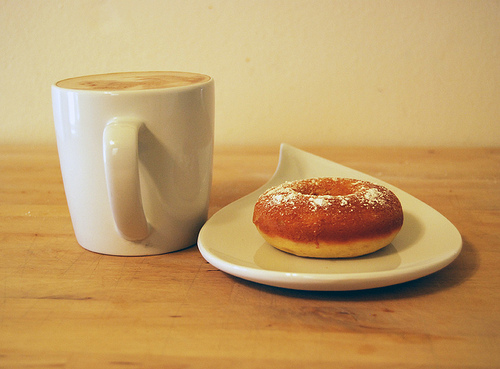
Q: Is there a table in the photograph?
A: Yes, there is a table.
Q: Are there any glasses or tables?
A: Yes, there is a table.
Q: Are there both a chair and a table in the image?
A: No, there is a table but no chairs.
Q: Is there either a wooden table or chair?
A: Yes, there is a wood table.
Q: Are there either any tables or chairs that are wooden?
A: Yes, the table is wooden.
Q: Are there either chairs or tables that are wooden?
A: Yes, the table is wooden.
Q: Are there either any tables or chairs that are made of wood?
A: Yes, the table is made of wood.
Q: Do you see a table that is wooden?
A: Yes, there is a wood table.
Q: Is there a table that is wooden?
A: Yes, there is a table that is wooden.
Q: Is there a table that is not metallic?
A: Yes, there is a wooden table.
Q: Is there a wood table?
A: Yes, there is a table that is made of wood.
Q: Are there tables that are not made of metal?
A: Yes, there is a table that is made of wood.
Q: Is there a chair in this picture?
A: No, there are no chairs.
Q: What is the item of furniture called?
A: The piece of furniture is a table.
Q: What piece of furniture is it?
A: The piece of furniture is a table.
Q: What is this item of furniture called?
A: This is a table.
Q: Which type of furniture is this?
A: This is a table.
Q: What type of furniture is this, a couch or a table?
A: This is a table.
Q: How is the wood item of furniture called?
A: The piece of furniture is a table.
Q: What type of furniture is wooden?
A: The furniture is a table.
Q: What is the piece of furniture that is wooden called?
A: The piece of furniture is a table.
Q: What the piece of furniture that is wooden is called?
A: The piece of furniture is a table.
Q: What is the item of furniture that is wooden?
A: The piece of furniture is a table.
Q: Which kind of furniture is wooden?
A: The furniture is a table.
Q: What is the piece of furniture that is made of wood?
A: The piece of furniture is a table.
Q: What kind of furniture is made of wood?
A: The furniture is a table.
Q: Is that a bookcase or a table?
A: That is a table.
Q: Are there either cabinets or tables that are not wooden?
A: No, there is a table but it is wooden.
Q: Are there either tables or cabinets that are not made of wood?
A: No, there is a table but it is made of wood.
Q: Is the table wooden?
A: Yes, the table is wooden.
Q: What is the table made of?
A: The table is made of wood.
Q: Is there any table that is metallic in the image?
A: No, there is a table but it is wooden.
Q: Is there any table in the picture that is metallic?
A: No, there is a table but it is wooden.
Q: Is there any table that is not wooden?
A: No, there is a table but it is wooden.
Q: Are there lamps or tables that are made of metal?
A: No, there is a table but it is made of wood.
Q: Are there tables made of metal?
A: No, there is a table but it is made of wood.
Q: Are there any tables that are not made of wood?
A: No, there is a table but it is made of wood.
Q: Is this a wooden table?
A: Yes, this is a wooden table.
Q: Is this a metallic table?
A: No, this is a wooden table.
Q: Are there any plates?
A: Yes, there is a plate.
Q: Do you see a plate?
A: Yes, there is a plate.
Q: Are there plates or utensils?
A: Yes, there is a plate.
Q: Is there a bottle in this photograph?
A: No, there are no bottles.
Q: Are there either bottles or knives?
A: No, there are no bottles or knives.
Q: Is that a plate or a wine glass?
A: That is a plate.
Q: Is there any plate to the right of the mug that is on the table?
A: Yes, there is a plate to the right of the mug.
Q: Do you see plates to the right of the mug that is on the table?
A: Yes, there is a plate to the right of the mug.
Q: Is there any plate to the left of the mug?
A: No, the plate is to the right of the mug.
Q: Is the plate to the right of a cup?
A: No, the plate is to the right of a mug.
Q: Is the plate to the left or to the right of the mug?
A: The plate is to the right of the mug.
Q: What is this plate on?
A: The plate is on the table.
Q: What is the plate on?
A: The plate is on the table.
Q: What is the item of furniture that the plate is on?
A: The piece of furniture is a table.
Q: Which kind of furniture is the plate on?
A: The plate is on the table.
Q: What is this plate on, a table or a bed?
A: The plate is on a table.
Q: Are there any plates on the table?
A: Yes, there is a plate on the table.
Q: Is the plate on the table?
A: Yes, the plate is on the table.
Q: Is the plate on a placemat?
A: No, the plate is on the table.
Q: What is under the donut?
A: The plate is under the donut.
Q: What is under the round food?
A: The plate is under the donut.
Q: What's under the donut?
A: The plate is under the donut.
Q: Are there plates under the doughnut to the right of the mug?
A: Yes, there is a plate under the donut.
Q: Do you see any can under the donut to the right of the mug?
A: No, there is a plate under the doughnut.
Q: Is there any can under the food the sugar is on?
A: No, there is a plate under the doughnut.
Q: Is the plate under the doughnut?
A: Yes, the plate is under the doughnut.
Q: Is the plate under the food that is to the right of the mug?
A: Yes, the plate is under the doughnut.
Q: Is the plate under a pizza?
A: No, the plate is under the doughnut.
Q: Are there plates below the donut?
A: Yes, there is a plate below the donut.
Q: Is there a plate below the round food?
A: Yes, there is a plate below the donut.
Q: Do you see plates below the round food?
A: Yes, there is a plate below the donut.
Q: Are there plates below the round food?
A: Yes, there is a plate below the donut.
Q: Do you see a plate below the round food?
A: Yes, there is a plate below the donut.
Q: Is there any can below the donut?
A: No, there is a plate below the donut.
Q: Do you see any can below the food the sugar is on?
A: No, there is a plate below the donut.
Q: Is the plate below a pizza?
A: No, the plate is below a donut.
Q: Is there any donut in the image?
A: Yes, there is a donut.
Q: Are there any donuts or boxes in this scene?
A: Yes, there is a donut.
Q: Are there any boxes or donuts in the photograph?
A: Yes, there is a donut.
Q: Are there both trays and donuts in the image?
A: No, there is a donut but no trays.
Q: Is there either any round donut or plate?
A: Yes, there is a round donut.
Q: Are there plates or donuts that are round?
A: Yes, the donut is round.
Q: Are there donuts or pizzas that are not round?
A: No, there is a donut but it is round.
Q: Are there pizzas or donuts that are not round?
A: No, there is a donut but it is round.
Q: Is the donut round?
A: Yes, the donut is round.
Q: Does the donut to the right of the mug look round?
A: Yes, the doughnut is round.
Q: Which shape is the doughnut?
A: The doughnut is round.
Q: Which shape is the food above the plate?
A: The doughnut is round.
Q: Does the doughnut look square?
A: No, the doughnut is round.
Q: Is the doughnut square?
A: No, the doughnut is round.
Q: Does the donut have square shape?
A: No, the donut is round.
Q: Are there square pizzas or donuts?
A: No, there is a donut but it is round.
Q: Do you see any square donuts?
A: No, there is a donut but it is round.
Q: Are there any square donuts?
A: No, there is a donut but it is round.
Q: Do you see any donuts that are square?
A: No, there is a donut but it is round.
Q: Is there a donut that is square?
A: No, there is a donut but it is round.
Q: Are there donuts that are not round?
A: No, there is a donut but it is round.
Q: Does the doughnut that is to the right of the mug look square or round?
A: The donut is round.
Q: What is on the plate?
A: The donut is on the plate.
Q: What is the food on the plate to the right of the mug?
A: The food is a donut.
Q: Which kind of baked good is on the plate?
A: The food is a donut.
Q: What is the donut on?
A: The donut is on the plate.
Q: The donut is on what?
A: The donut is on the plate.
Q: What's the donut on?
A: The donut is on the plate.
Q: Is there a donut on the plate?
A: Yes, there is a donut on the plate.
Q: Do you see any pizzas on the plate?
A: No, there is a donut on the plate.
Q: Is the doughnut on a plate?
A: Yes, the doughnut is on a plate.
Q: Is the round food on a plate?
A: Yes, the doughnut is on a plate.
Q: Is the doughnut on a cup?
A: No, the doughnut is on a plate.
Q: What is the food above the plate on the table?
A: The food is a donut.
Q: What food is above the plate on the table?
A: The food is a donut.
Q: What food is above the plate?
A: The food is a donut.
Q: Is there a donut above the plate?
A: Yes, there is a donut above the plate.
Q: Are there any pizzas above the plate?
A: No, there is a donut above the plate.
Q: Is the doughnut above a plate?
A: Yes, the doughnut is above a plate.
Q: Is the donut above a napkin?
A: No, the donut is above a plate.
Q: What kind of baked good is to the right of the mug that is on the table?
A: The food is a donut.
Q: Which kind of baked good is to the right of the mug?
A: The food is a donut.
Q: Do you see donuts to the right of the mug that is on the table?
A: Yes, there is a donut to the right of the mug.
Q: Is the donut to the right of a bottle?
A: No, the donut is to the right of the mug.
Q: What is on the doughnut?
A: The sugar is on the doughnut.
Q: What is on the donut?
A: The sugar is on the doughnut.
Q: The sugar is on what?
A: The sugar is on the donut.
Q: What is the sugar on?
A: The sugar is on the donut.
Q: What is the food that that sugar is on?
A: The food is a donut.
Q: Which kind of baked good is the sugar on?
A: The sugar is on the donut.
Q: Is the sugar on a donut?
A: Yes, the sugar is on a donut.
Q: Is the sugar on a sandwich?
A: No, the sugar is on a donut.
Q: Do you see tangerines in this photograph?
A: No, there are no tangerines.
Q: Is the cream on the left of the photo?
A: Yes, the cream is on the left of the image.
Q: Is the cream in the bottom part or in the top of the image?
A: The cream is in the top of the image.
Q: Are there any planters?
A: No, there are no planters.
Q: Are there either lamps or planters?
A: No, there are no planters or lamps.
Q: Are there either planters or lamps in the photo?
A: No, there are no planters or lamps.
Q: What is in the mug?
A: The liquid is in the mug.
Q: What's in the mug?
A: The liquid is in the mug.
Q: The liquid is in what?
A: The liquid is in the mug.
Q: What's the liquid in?
A: The liquid is in the mug.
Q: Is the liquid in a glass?
A: No, the liquid is in the mug.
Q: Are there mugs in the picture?
A: Yes, there is a mug.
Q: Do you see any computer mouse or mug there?
A: Yes, there is a mug.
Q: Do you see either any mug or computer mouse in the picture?
A: Yes, there is a mug.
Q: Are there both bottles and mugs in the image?
A: No, there is a mug but no bottles.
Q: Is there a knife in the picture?
A: No, there are no knives.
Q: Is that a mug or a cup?
A: That is a mug.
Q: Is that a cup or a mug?
A: That is a mug.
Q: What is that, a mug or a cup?
A: That is a mug.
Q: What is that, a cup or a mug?
A: That is a mug.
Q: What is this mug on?
A: The mug is on the table.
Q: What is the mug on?
A: The mug is on the table.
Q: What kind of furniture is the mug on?
A: The mug is on the table.